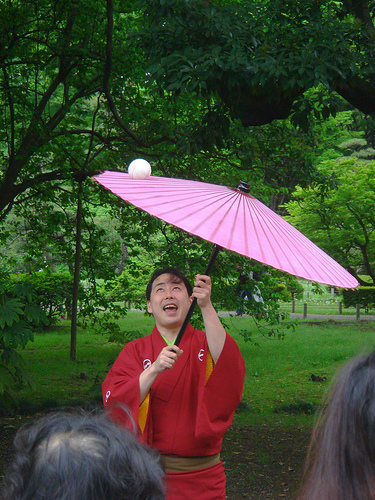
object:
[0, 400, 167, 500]
hair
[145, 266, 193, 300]
hair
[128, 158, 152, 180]
baseball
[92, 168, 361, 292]
umbrella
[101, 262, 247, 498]
person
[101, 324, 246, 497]
outfit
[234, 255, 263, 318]
people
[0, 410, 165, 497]
man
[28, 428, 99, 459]
bald spot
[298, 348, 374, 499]
woman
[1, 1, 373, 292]
trees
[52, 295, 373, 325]
sidewalk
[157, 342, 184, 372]
right hand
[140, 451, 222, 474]
sash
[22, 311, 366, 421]
grass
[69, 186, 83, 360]
trunk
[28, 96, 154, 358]
tree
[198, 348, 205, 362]
design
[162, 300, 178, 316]
mouth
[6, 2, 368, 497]
park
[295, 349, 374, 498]
hair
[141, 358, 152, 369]
design